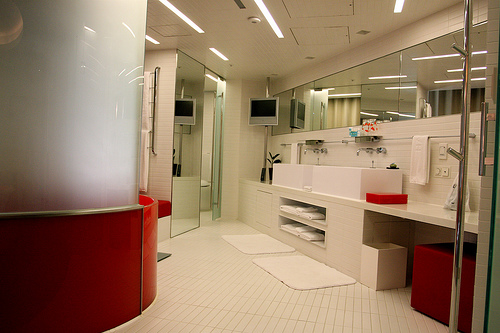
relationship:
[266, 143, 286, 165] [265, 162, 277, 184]
plant in a pot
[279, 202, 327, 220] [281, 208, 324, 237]
towels on shelf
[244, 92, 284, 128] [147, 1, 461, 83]
monitor mounted on ceiling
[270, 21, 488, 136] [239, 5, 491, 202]
mirror mounted on wall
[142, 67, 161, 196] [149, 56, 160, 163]
towels on towel rack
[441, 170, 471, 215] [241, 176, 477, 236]
bag on counter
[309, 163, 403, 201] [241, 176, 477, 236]
sink on counter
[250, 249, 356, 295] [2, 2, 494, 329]
rug in bathroom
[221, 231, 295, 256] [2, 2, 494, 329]
rug in bathroom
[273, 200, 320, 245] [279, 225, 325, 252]
towels on shelf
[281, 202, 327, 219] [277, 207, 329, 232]
towels on shelf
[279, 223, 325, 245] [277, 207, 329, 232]
towels on shelf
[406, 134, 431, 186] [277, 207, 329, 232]
towels on shelf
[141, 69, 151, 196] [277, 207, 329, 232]
towels on shelf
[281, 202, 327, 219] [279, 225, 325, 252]
towels on shelf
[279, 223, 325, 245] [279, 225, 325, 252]
towels on shelf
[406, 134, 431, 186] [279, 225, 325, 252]
towels on shelf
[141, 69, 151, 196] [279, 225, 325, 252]
towels on shelf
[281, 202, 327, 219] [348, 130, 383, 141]
towels on shelf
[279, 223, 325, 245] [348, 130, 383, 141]
towels on shelf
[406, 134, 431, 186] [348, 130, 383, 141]
towels on shelf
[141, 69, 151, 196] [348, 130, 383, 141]
towels on shelf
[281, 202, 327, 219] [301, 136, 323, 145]
towels on shelf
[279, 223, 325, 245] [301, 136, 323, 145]
towels on shelf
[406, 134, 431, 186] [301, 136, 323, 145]
towels on shelf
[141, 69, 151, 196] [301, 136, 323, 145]
towels on shelf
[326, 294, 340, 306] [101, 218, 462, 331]
tile on floor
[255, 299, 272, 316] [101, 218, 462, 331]
tile on floor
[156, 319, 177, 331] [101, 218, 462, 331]
tile on floor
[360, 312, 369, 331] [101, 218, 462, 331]
tile on floor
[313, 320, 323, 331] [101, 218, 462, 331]
tile on floor